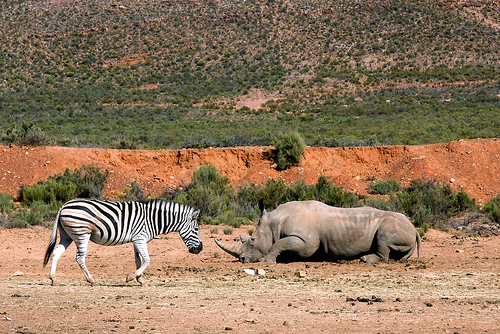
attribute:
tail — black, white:
[28, 209, 61, 263]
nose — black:
[174, 234, 205, 254]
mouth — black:
[183, 232, 211, 256]